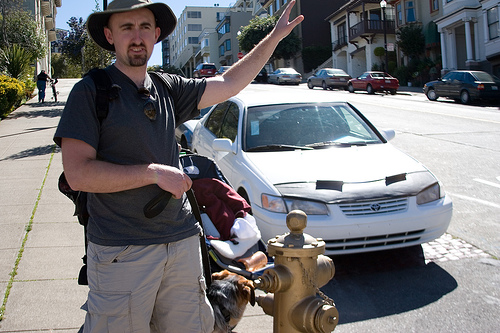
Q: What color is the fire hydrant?
A: Gold.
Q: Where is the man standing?
A: On the sidewalk.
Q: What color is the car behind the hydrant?
A: White.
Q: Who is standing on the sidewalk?
A: A man.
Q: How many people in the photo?
A: Two.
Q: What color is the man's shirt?
A: Black.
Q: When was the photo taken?
A: Daytime.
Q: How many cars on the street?
A: Seven.